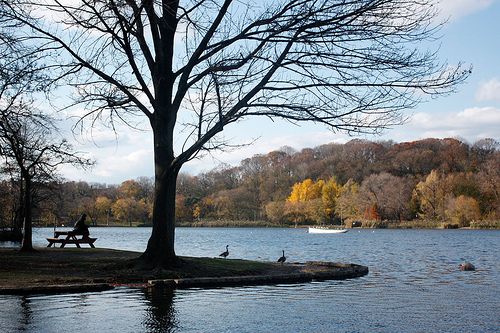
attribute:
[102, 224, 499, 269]
water — large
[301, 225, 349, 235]
boat — white, small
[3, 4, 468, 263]
tree — large, yellow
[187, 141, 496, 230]
trees — large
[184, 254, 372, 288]
peninsula — small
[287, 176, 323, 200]
tree — yellow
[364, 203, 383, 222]
tree — red